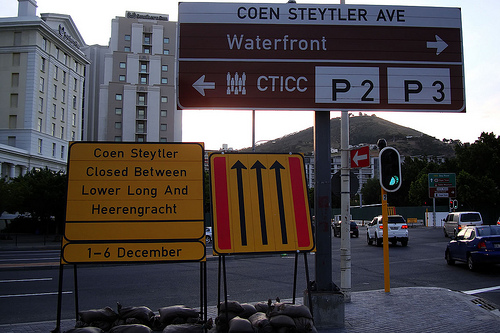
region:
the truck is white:
[365, 215, 408, 241]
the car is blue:
[440, 225, 497, 270]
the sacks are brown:
[82, 271, 322, 322]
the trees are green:
[415, 150, 490, 205]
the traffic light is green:
[388, 173, 400, 189]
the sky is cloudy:
[200, 115, 280, 130]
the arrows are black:
[217, 155, 298, 255]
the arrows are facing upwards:
[215, 160, 290, 242]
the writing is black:
[85, 146, 183, 219]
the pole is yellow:
[378, 200, 393, 285]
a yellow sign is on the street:
[67, 139, 204, 262]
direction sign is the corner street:
[179, 3, 468, 116]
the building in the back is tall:
[88, 8, 186, 150]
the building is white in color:
[2, 0, 90, 177]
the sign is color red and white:
[350, 144, 372, 170]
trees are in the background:
[363, 130, 498, 251]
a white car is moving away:
[365, 213, 409, 246]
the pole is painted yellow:
[373, 148, 400, 299]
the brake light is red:
[379, 223, 408, 230]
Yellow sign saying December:
[117, 245, 185, 260]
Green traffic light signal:
[375, 144, 403, 298]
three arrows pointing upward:
[229, 152, 297, 254]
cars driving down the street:
[351, 210, 498, 277]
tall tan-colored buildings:
[3, 6, 188, 141]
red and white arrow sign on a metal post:
[342, 141, 372, 224]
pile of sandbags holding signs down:
[72, 299, 317, 330]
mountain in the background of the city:
[224, 111, 466, 165]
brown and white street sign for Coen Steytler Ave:
[180, 4, 460, 107]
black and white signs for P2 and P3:
[322, 69, 446, 106]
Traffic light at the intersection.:
[332, 118, 492, 242]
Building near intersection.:
[88, 15, 199, 222]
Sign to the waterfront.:
[216, 15, 463, 135]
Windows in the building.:
[30, 33, 105, 195]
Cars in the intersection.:
[380, 190, 483, 257]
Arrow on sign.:
[337, 123, 377, 200]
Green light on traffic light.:
[378, 162, 420, 221]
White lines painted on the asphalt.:
[19, 245, 60, 331]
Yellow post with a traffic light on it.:
[368, 176, 405, 320]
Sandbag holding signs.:
[215, 275, 284, 320]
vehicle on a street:
[363, 208, 415, 250]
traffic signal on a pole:
[362, 132, 406, 214]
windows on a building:
[50, 82, 80, 132]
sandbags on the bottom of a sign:
[211, 279, 318, 331]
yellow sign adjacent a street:
[42, 128, 209, 330]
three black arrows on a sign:
[206, 147, 318, 264]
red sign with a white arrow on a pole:
[333, 137, 374, 181]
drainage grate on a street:
[461, 286, 497, 319]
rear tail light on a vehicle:
[397, 221, 411, 233]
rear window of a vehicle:
[457, 210, 483, 225]